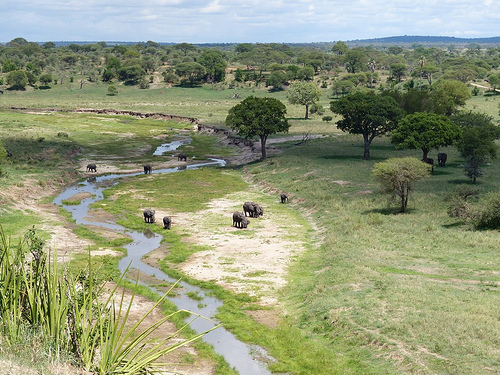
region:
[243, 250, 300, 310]
part of a grpounmd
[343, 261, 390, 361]
part of a field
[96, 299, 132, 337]
part of a nappier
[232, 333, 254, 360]
part of a ibver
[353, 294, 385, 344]
part of a grpound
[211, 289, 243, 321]
part of a river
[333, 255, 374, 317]
part of a ground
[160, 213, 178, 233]
An elephant in the field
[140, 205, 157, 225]
An elephant in the field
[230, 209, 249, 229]
A group of elephants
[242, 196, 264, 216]
A group of elephants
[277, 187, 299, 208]
An elephant in the field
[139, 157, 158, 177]
An elephant in the field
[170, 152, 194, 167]
An elephant in the field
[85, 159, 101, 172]
An elephant in the field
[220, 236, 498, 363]
A grassy savannah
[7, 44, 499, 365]
A grassy field with a stream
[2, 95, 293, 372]
stream curving through grassy flatlands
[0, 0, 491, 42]
blue sky filled with clouds over low mountain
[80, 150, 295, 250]
herd of elephants near stream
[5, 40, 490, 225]
trees growing near and far from stream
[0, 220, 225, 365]
plants with long pointy leaves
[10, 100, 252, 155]
curved rim separating levels of ground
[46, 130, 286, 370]
water reflecting blue sky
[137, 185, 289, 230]
adult and young elephants standing on low ground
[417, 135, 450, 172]
elephants under shade of tree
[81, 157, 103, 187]
reflection of elephant on water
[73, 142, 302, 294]
a bunch of elephants in a field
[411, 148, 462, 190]
a couple elephants under the trees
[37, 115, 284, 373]
a small stream of water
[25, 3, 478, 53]
white clouds in the sky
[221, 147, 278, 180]
shadow on ground under tree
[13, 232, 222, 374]
long skinny leaves to plant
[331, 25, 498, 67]
a mountain in the distance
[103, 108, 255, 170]
a ridge along the water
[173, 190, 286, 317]
a white patch in the grass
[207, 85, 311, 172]
one tree close to the water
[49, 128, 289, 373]
A small stream of water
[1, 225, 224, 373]
A patch of tall grass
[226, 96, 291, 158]
A large tall tree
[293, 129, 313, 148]
A large branch on the ground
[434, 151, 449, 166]
an elephant under a tree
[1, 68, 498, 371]
A large grassy landscape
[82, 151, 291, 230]
A small herd of elephants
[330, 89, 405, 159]
A large tall tree